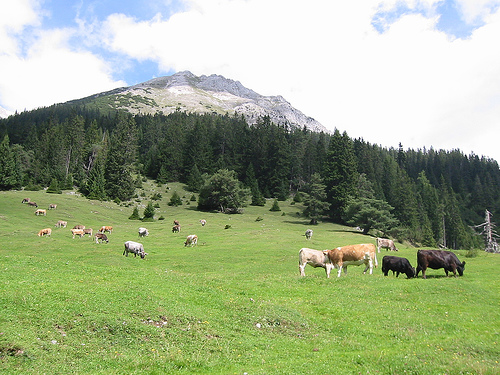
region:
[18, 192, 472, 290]
A heard of cattle.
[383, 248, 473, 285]
Two black cows.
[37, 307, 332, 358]
Patches of dirt in grass field.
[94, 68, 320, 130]
The rocky mountain top.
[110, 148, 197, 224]
Small bushes on the hill.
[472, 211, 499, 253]
A dead tree.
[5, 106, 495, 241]
A large forest on the hill.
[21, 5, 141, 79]
The cloudy sky.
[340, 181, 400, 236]
The tree tilted sideways.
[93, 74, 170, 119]
Trees on the mountain side.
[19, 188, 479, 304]
large herd of cows on a hill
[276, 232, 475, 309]
black brown and withe cows grazing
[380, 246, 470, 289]
mother cow with her baby cow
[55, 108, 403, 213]
evergreen forest on the side of the mountain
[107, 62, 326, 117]
stony top of the mountain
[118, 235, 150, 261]
white cow on the side of the mountain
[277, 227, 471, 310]
cows ambling about a grassy hillside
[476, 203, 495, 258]
broken and spiny dead pine tree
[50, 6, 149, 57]
fluffy white clouds in the sky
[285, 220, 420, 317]
cows on the grass in the sun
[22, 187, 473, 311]
over a dozen cows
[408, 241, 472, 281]
dark brown cow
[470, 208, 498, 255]
dead decaying grey tree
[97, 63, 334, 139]
grey stony mountain top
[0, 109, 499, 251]
dense forest of ever greens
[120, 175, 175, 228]
small rocky valley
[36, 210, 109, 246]
group of beige coloured cows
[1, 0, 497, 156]
blue partly cloudy sky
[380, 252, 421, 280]
black coloured cow grazing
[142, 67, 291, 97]
shadowed area of mountain top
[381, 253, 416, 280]
Black cow on green field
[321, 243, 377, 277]
Brown cow on green field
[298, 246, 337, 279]
White cow on green field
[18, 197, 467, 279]
Cows grazing on green field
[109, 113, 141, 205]
Tall green tree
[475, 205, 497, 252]
Leafless tree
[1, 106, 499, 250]
Field of green trees in front of mountain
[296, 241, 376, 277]
White cow near brown cow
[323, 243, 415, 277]
Brown cow near black cow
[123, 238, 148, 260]
White cow grazing alone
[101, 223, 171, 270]
cow in an open field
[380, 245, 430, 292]
black cow in a field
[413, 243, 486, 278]
black cow in a field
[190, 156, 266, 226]
shrub in a field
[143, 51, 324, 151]
mountain in the field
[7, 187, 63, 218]
cows in a field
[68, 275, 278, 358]
grass in an open field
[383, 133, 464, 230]
trees in an open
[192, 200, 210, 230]
cow in an open field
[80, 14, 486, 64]
sky over an open field